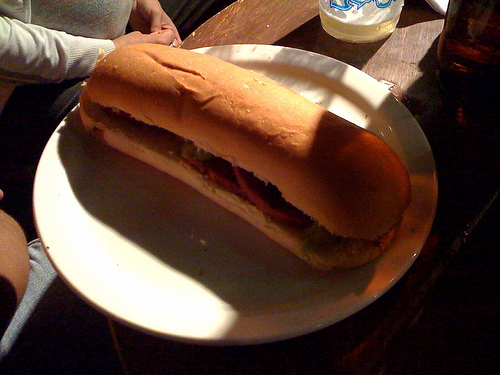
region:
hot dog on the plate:
[60, 32, 396, 267]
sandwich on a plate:
[62, 27, 399, 286]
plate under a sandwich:
[15, 126, 292, 362]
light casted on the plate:
[46, 184, 108, 301]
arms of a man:
[9, 1, 182, 71]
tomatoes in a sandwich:
[173, 137, 323, 244]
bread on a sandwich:
[152, 53, 284, 151]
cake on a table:
[307, 1, 414, 45]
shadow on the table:
[420, 92, 489, 354]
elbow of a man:
[1, 188, 40, 335]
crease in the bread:
[148, 48, 209, 99]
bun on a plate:
[81, 62, 153, 114]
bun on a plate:
[70, 112, 139, 154]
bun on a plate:
[121, 143, 183, 173]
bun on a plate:
[302, 248, 347, 270]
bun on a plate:
[325, 183, 412, 235]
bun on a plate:
[277, 150, 358, 207]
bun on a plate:
[215, 141, 301, 190]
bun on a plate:
[234, 90, 296, 112]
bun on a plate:
[305, 118, 359, 145]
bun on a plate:
[228, 70, 268, 89]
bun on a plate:
[93, 116, 148, 163]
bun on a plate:
[141, 133, 187, 175]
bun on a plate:
[300, 189, 336, 214]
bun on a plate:
[320, 113, 410, 173]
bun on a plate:
[268, 88, 328, 141]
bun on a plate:
[227, 80, 283, 130]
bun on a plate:
[185, 62, 240, 104]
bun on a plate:
[153, 58, 202, 83]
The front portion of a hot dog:
[242, 121, 419, 286]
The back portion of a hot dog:
[77, 36, 169, 155]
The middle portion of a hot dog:
[158, 71, 288, 205]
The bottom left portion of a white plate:
[50, 171, 243, 356]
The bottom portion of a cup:
[302, 3, 409, 48]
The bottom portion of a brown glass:
[408, 23, 499, 69]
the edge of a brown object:
[0, 201, 27, 296]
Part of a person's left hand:
[137, 0, 177, 27]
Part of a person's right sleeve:
[0, 15, 93, 80]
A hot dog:
[62, 10, 401, 283]